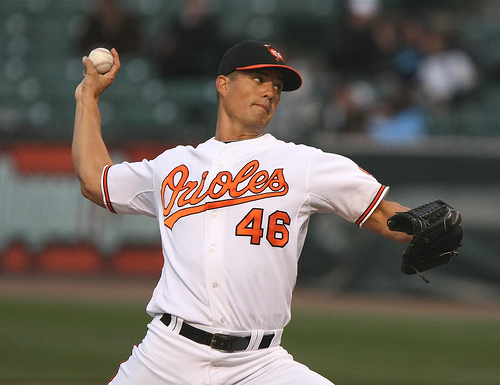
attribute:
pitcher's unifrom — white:
[101, 130, 388, 383]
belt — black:
[158, 311, 273, 354]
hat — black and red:
[214, 41, 301, 89]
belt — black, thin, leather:
[151, 309, 286, 355]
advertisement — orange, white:
[1, 142, 178, 276]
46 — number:
[231, 203, 293, 254]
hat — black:
[208, 39, 303, 97]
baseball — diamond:
[86, 45, 113, 77]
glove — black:
[386, 185, 471, 290]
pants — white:
[97, 282, 298, 382]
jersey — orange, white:
[108, 140, 358, 381]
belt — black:
[157, 314, 282, 351]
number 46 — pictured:
[223, 194, 321, 242]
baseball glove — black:
[383, 196, 467, 280]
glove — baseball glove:
[385, 198, 464, 275]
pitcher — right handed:
[58, 31, 447, 380]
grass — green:
[2, 299, 498, 381]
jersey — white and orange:
[91, 125, 397, 346]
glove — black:
[383, 196, 468, 283]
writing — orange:
[162, 158, 289, 230]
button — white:
[213, 282, 218, 287]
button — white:
[220, 317, 225, 322]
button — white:
[208, 243, 217, 251]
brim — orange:
[239, 60, 306, 90]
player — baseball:
[62, 24, 469, 382]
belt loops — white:
[168, 315, 188, 333]